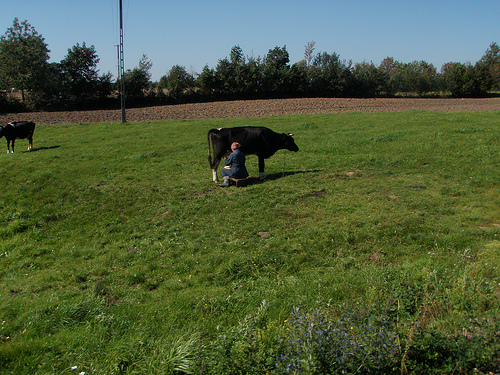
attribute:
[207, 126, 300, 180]
cow — black, large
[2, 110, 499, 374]
meadow — green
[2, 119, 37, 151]
cow — black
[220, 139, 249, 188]
person — milking, sitting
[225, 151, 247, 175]
jacket — blue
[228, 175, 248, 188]
stool — brown, rectangle, wooden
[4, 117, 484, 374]
grass — green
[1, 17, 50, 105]
tree — green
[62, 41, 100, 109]
tree — green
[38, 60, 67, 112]
tree — green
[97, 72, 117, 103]
tree — green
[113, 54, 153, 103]
tree — green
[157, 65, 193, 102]
tree — green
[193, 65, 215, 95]
tree — green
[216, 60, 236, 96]
tree — green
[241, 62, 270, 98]
tree — green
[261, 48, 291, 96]
tree — green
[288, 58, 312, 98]
tree — green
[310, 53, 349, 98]
tree — green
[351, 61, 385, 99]
tree — green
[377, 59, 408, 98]
tree — green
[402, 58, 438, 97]
tree — green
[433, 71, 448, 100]
tree — green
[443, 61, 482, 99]
tree — green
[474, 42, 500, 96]
tree — green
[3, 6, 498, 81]
sky — blue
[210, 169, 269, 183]
feet — white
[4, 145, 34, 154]
feet — white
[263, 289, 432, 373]
flowers — blue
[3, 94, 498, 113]
soil — brown, tilled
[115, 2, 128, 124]
tower — metal, tall, electrical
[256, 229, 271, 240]
spot — brown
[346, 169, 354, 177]
spot — brown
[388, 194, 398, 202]
spot — brown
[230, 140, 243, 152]
hat — red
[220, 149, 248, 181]
clothing — blue